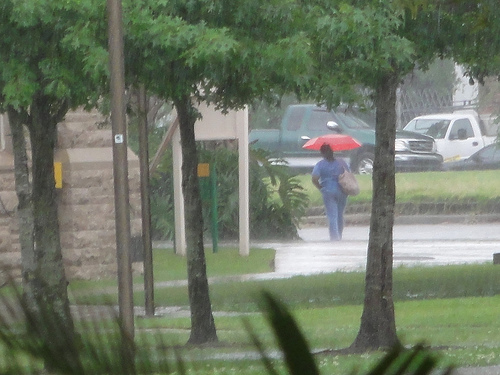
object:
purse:
[338, 160, 361, 196]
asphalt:
[275, 222, 497, 260]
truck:
[402, 109, 498, 167]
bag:
[338, 158, 360, 196]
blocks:
[71, 164, 144, 277]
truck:
[251, 103, 444, 177]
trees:
[278, 0, 499, 354]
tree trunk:
[356, 92, 398, 336]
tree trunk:
[174, 88, 218, 334]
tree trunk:
[29, 128, 74, 331]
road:
[274, 221, 498, 279]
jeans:
[322, 186, 348, 241]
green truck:
[249, 104, 444, 175]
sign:
[196, 162, 210, 177]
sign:
[112, 134, 124, 144]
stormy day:
[60, 57, 491, 318]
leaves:
[0, 0, 500, 117]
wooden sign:
[175, 139, 244, 259]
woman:
[309, 143, 361, 241]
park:
[166, 115, 500, 306]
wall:
[58, 162, 113, 269]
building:
[0, 98, 156, 286]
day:
[5, 2, 499, 362]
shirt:
[312, 157, 352, 194]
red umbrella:
[302, 133, 361, 152]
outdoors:
[0, 0, 498, 372]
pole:
[103, 2, 136, 348]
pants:
[322, 191, 347, 238]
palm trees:
[146, 143, 309, 240]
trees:
[130, 0, 275, 346]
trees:
[0, 0, 107, 346]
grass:
[0, 260, 460, 375]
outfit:
[311, 158, 360, 239]